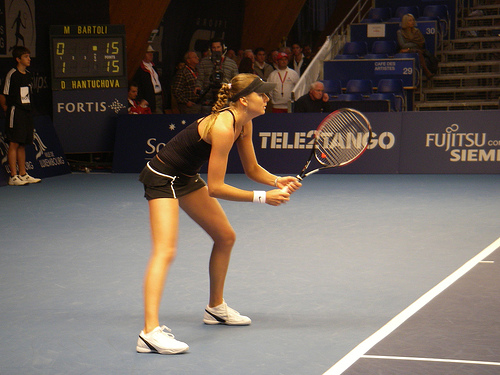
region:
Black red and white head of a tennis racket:
[307, 94, 372, 175]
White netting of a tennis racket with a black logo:
[320, 117, 365, 151]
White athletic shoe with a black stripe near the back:
[109, 318, 191, 359]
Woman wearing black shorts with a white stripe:
[134, 145, 216, 230]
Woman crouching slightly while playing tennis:
[147, 56, 382, 244]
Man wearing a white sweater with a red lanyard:
[262, 37, 299, 119]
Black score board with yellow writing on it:
[55, 20, 127, 98]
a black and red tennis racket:
[260, 79, 378, 220]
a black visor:
[229, 70, 290, 110]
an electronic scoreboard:
[36, 21, 138, 98]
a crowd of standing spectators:
[126, 31, 298, 106]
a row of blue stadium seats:
[319, 9, 435, 101]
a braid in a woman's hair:
[191, 74, 231, 134]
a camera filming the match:
[190, 52, 242, 113]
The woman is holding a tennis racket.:
[97, 55, 382, 363]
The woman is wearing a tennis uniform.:
[112, 55, 379, 368]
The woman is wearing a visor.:
[127, 50, 309, 357]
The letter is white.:
[53, 98, 68, 122]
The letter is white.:
[61, 100, 78, 117]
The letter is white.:
[73, 98, 88, 118]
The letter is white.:
[83, 95, 96, 116]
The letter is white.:
[96, 98, 108, 118]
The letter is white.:
[447, 145, 463, 170]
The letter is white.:
[141, 131, 158, 162]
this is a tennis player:
[120, 56, 384, 366]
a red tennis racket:
[263, 68, 382, 217]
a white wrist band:
[244, 175, 273, 215]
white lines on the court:
[306, 228, 498, 371]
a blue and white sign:
[116, 115, 495, 182]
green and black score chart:
[41, 22, 134, 90]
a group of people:
[126, 32, 314, 112]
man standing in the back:
[6, 41, 47, 197]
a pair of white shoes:
[106, 300, 263, 367]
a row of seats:
[306, 66, 411, 108]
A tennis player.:
[120, 68, 376, 355]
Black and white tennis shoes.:
[133, 305, 253, 352]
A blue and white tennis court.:
[12, 160, 497, 373]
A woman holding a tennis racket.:
[125, 66, 372, 356]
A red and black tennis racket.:
[282, 96, 376, 208]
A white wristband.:
[254, 187, 265, 206]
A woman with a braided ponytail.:
[138, 70, 304, 358]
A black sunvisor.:
[230, 76, 277, 102]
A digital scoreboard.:
[50, 33, 130, 83]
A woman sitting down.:
[390, 10, 432, 76]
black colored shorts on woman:
[127, 151, 208, 201]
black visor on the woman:
[225, 72, 275, 99]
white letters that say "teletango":
[245, 122, 402, 157]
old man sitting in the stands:
[283, 75, 340, 110]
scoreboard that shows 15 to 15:
[38, 18, 127, 114]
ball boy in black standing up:
[9, 45, 55, 187]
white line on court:
[308, 231, 498, 373]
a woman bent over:
[106, 73, 496, 315]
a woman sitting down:
[395, 14, 424, 65]